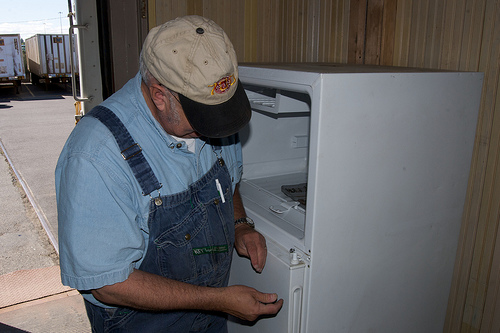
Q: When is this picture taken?
A: During the day.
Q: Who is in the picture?
A: Man.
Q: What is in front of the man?
A: Fridge.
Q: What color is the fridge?
A: White.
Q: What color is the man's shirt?
A: Blue.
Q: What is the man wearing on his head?
A: A cap.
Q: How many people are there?
A: One.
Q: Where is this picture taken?
A: Fixing the fridge.